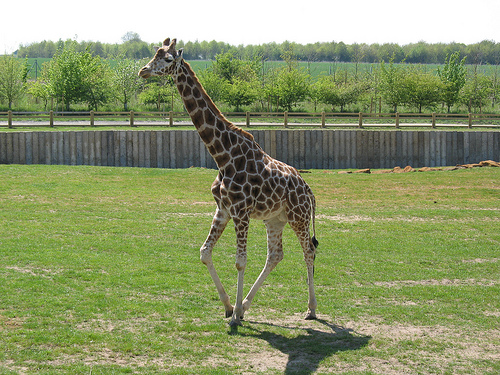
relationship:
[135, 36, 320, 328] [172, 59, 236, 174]
giraffe has a neck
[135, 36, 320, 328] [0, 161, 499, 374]
giraffe on grass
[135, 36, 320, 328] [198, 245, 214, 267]
giraffe has a knee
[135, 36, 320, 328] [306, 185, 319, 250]
giraffe has a tail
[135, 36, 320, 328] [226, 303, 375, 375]
giraffe has a shadow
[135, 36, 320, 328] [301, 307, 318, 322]
giraffe has a hoof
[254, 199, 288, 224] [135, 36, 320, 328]
stomach of giraffe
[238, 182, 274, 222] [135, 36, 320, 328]
chest of giraffe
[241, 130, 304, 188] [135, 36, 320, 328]
back of giraffe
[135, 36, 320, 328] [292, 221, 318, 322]
giraffe has a leg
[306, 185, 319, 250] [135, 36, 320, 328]
tail of giraffe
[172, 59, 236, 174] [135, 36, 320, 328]
neck of giraffe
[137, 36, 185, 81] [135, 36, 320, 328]
head of giraffe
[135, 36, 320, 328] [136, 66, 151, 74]
giraffe has a nose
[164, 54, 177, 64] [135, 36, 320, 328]
eye of giraffe